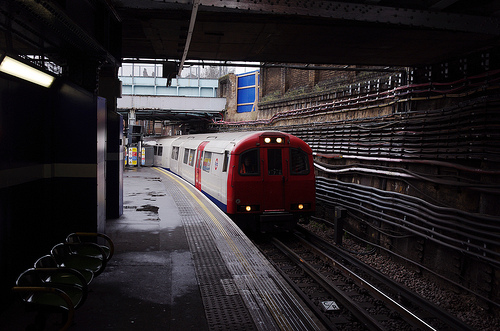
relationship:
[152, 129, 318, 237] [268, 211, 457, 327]
train on tracks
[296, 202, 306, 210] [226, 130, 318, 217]
light on front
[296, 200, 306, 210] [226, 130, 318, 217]
light on front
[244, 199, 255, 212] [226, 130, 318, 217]
light on front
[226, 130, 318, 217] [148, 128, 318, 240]
front of train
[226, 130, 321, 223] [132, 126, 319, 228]
front of train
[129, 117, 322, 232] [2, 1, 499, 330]
train coming into station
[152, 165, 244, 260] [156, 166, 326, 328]
line on edge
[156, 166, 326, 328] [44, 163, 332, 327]
edge of platform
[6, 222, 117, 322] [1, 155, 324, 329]
empty seats on platform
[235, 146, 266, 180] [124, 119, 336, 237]
window on train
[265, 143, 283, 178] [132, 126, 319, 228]
window on train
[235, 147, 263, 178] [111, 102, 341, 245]
window on train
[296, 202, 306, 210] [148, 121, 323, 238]
light on train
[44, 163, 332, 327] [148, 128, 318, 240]
platform on train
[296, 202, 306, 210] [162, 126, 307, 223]
light on train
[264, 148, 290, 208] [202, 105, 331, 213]
door on train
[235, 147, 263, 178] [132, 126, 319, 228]
window on train